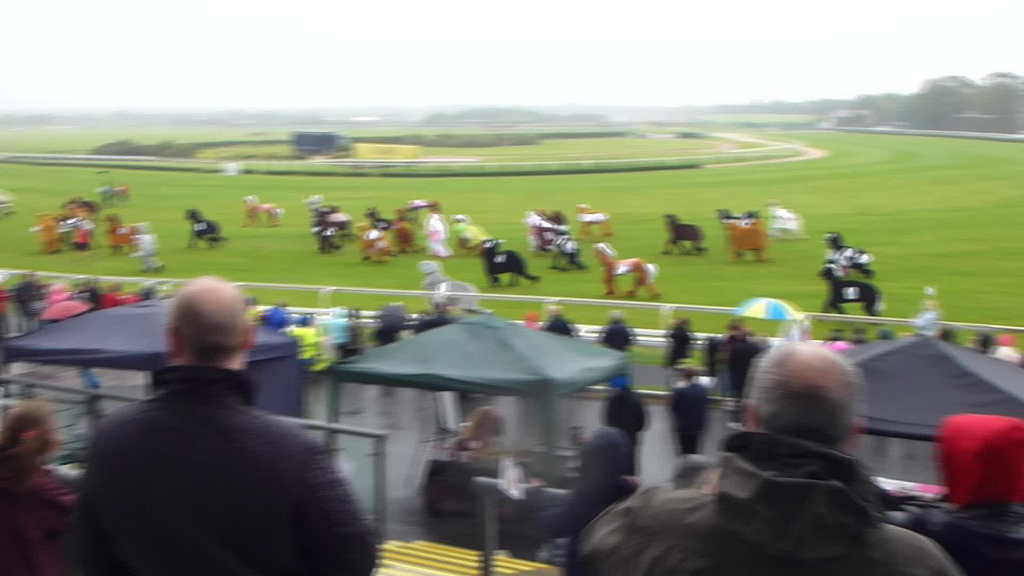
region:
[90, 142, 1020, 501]
this is a race track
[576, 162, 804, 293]
the track is grassy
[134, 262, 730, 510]
the people are gathered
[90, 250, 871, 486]
the people are watching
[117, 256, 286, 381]
the man is bald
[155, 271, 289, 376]
the head of a man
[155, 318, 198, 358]
the left ear of a man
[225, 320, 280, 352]
the right ear of a man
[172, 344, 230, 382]
the neck of a man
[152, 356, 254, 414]
the collar of a man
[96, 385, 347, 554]
the jacket of a man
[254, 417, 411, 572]
the right arm of a man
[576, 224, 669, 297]
a horse that is brown and white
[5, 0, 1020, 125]
a cloudy white sky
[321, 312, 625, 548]
a tent near a race track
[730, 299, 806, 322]
a yellow and turquoise umbrella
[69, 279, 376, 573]
a man in a black jacket at a track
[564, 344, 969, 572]
a man in a gray jacket near a track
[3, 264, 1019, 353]
a silver rail around a race track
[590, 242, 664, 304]
a light brown horse on the grass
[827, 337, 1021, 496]
a black tent near a track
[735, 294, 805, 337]
Blue and yellow umbrella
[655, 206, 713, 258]
Dark horse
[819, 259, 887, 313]
Dark horse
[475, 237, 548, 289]
Dark horse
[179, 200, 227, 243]
Dark horse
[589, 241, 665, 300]
Light brown horse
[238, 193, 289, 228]
Light brown horse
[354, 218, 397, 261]
Light brown horse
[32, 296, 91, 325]
Pink umbrella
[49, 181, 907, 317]
Horses are running in the grass.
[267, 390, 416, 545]
rail is grey color.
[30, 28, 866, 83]
Sky is white color.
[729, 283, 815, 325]
Umbrella is yellow and blue color.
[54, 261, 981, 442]
Tent is grey color.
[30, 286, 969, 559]
People are watching the horses.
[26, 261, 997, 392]
Fence is white color.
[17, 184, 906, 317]
bunch of horses on field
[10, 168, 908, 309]
bunch of horses on field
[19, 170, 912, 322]
bunch of horses on field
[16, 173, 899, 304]
bunch of horses on field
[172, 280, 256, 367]
person has a head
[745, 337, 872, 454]
person has a head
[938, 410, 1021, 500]
person has a head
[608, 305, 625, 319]
person has a headperson has a head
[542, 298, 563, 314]
person has a head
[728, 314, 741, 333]
person has a head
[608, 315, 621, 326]
person has a head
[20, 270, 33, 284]
person has a head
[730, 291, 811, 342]
The umbrella is blue and yellow.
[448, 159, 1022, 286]
The grass is green.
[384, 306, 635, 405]
The top of tent is green.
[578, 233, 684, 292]
Pony on the grass.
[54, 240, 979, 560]
the picture is blurry.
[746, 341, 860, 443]
Man hair is gray and white.